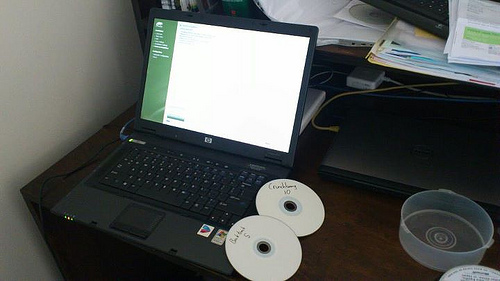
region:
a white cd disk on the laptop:
[261, 178, 323, 231]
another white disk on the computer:
[229, 218, 301, 275]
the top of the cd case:
[391, 184, 491, 269]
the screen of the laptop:
[151, 18, 283, 138]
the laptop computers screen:
[142, 24, 289, 153]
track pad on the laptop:
[125, 198, 157, 240]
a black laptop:
[66, 4, 311, 254]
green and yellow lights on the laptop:
[58, 212, 75, 225]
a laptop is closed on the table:
[316, 100, 498, 200]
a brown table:
[333, 202, 380, 274]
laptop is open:
[44, 11, 324, 279]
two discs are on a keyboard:
[217, 174, 327, 279]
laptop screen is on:
[137, 6, 322, 172]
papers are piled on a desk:
[251, 0, 499, 96]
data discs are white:
[217, 172, 327, 279]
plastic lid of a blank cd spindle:
[385, 181, 494, 275]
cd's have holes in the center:
[219, 168, 326, 280]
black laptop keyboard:
[37, 128, 305, 275]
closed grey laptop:
[311, 71, 499, 221]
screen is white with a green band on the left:
[132, 3, 318, 167]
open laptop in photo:
[40, 16, 352, 263]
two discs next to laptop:
[205, 183, 329, 279]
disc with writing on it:
[258, 169, 319, 222]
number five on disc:
[238, 230, 255, 245]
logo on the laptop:
[193, 127, 220, 155]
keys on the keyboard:
[131, 143, 223, 198]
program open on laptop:
[155, 34, 287, 106]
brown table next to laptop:
[325, 213, 380, 258]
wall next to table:
[0, 22, 92, 114]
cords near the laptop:
[339, 64, 431, 135]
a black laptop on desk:
[52, 8, 319, 280]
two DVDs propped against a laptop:
[225, 173, 326, 280]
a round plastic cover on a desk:
[396, 185, 493, 270]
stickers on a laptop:
[194, 222, 228, 247]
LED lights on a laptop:
[62, 213, 74, 221]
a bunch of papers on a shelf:
[256, 0, 498, 90]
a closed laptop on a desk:
[322, 97, 499, 216]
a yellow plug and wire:
[310, 78, 457, 135]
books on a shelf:
[149, 0, 255, 16]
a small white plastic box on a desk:
[344, 65, 387, 91]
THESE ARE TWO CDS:
[207, 162, 337, 278]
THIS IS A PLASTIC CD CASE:
[390, 175, 493, 278]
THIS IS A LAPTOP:
[42, 5, 328, 275]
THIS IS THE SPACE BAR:
[130, 175, 183, 211]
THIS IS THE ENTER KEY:
[220, 180, 262, 228]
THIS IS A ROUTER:
[302, 76, 497, 239]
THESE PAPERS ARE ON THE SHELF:
[362, 3, 497, 89]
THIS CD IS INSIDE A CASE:
[336, 0, 403, 43]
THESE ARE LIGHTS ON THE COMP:
[51, 207, 78, 228]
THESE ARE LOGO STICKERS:
[185, 218, 229, 255]